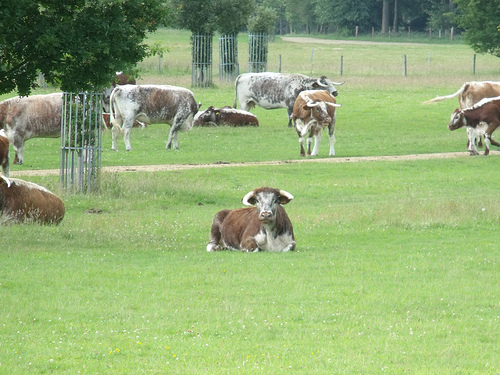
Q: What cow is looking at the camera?
A: The center-most cow.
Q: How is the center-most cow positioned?
A: Lying down on the grass.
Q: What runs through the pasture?
A: A dirt path.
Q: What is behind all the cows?
A: A fence.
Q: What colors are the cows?
A: White and brown.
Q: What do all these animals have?
A: Horns.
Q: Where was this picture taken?
A: On a dairy farm.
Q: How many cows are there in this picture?
A: 10.